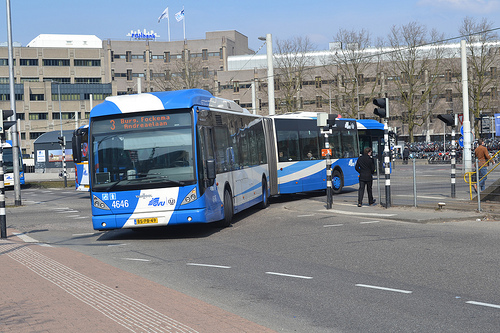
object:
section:
[250, 225, 383, 302]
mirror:
[206, 158, 217, 179]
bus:
[71, 87, 384, 231]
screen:
[92, 113, 191, 133]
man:
[354, 147, 377, 207]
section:
[11, 131, 21, 201]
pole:
[7, 0, 22, 207]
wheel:
[223, 189, 233, 225]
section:
[33, 49, 73, 58]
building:
[215, 41, 500, 145]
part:
[37, 66, 74, 78]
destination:
[119, 114, 169, 130]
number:
[111, 199, 130, 209]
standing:
[371, 92, 394, 206]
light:
[373, 96, 390, 118]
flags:
[174, 9, 185, 24]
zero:
[383, 15, 452, 142]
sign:
[125, 27, 160, 42]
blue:
[306, 180, 322, 188]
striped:
[277, 160, 324, 178]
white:
[385, 179, 391, 186]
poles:
[461, 39, 471, 174]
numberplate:
[133, 217, 159, 226]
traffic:
[0, 109, 19, 134]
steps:
[473, 193, 500, 201]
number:
[109, 119, 116, 130]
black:
[386, 186, 390, 201]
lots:
[0, 58, 101, 67]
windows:
[276, 129, 301, 162]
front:
[104, 38, 228, 97]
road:
[0, 159, 500, 333]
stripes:
[265, 271, 316, 280]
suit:
[354, 153, 376, 205]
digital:
[92, 112, 193, 135]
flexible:
[262, 115, 280, 197]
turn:
[72, 88, 385, 231]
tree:
[318, 27, 382, 119]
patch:
[208, 0, 274, 29]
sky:
[0, 0, 500, 56]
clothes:
[355, 154, 375, 181]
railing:
[463, 150, 500, 200]